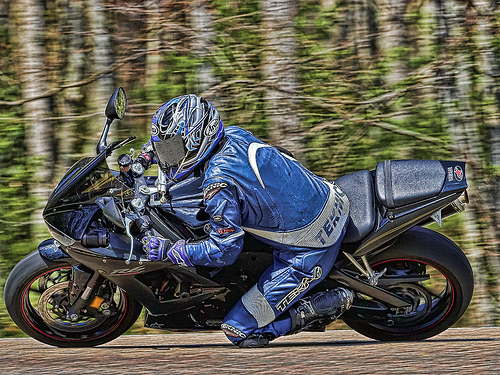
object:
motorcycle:
[4, 87, 474, 347]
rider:
[142, 94, 353, 347]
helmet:
[150, 94, 223, 183]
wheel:
[4, 252, 141, 348]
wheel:
[344, 227, 474, 343]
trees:
[2, 0, 498, 326]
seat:
[333, 160, 446, 243]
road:
[0, 327, 499, 373]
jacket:
[169, 126, 349, 267]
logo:
[248, 143, 299, 189]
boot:
[287, 287, 353, 335]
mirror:
[105, 87, 127, 120]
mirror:
[103, 200, 126, 229]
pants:
[221, 229, 348, 347]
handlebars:
[130, 148, 154, 243]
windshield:
[44, 141, 136, 208]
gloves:
[143, 236, 194, 266]